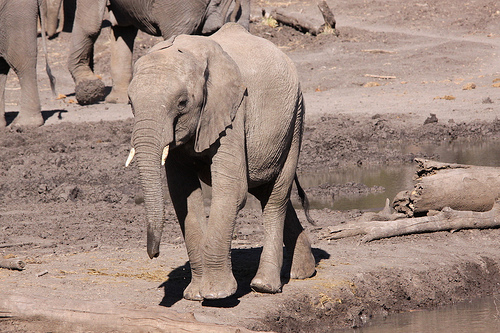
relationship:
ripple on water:
[459, 306, 489, 327] [357, 284, 496, 330]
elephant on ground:
[0, 0, 317, 302] [1, 59, 487, 303]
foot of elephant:
[200, 269, 237, 301] [121, 20, 318, 304]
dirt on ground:
[42, 166, 156, 291] [45, 126, 460, 311]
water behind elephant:
[357, 284, 496, 330] [121, 20, 318, 304]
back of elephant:
[223, 30, 258, 52] [115, 20, 334, 313]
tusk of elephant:
[123, 144, 144, 169] [121, 20, 318, 304]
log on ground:
[392, 153, 499, 232] [4, 3, 482, 326]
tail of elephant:
[287, 165, 324, 240] [115, 20, 334, 313]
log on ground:
[319, 157, 499, 244] [317, 238, 498, 279]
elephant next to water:
[121, 20, 318, 304] [331, 288, 498, 330]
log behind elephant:
[319, 157, 499, 244] [99, 17, 364, 307]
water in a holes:
[291, 145, 434, 225] [244, 128, 498, 323]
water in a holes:
[337, 291, 497, 331] [358, 309, 374, 319]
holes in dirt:
[244, 128, 498, 323] [257, 1, 498, 51]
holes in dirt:
[358, 309, 374, 319] [257, 1, 498, 51]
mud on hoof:
[75, 79, 111, 108] [67, 71, 111, 111]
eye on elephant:
[177, 97, 189, 109] [121, 20, 318, 304]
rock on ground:
[256, 0, 338, 44] [4, 3, 482, 326]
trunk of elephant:
[129, 111, 170, 257] [129, 116, 172, 261]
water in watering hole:
[337, 291, 500, 333] [198, 133, 499, 331]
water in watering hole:
[357, 284, 496, 330] [266, 255, 498, 329]